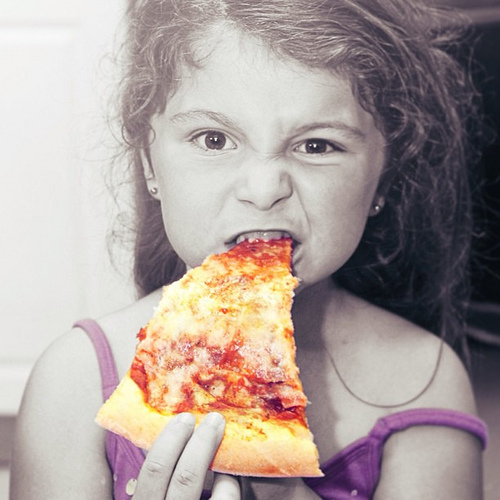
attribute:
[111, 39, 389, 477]
girl — angry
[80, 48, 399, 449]
girl — small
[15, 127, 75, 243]
wall — white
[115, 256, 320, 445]
pizza — cheese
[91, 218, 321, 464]
pizza — cheese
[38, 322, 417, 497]
tank top — purple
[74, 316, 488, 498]
dress — purple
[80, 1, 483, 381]
hair — long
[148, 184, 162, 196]
earring — round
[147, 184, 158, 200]
earring — silver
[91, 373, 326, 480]
crust — brown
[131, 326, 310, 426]
sauce — red